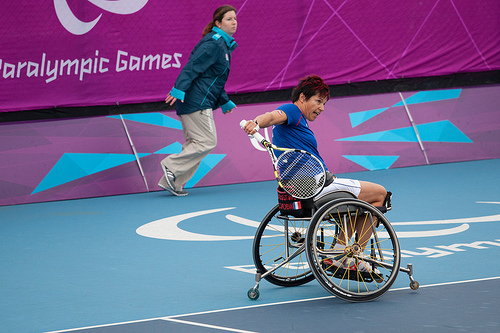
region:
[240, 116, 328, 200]
tennis racket in woman's hand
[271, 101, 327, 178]
blue t-shirt on woman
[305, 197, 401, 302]
wheel on woman's wheelchair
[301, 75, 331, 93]
dark red highlights in woman's hair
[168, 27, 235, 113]
blue jacket on girl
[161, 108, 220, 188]
khaki pants on girl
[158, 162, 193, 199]
beige sneakers on girl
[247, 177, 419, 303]
wheelchair with woman sitting in it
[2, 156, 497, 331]
floor of tennis court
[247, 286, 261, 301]
stabilizing wheel on wheelchair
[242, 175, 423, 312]
part of a wheelchair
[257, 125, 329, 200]
a large tennis racket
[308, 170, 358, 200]
part of a woman's white shorts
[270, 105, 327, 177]
part of a short sleeve blue shirt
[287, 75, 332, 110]
a woman's short cut hair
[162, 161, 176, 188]
part of a woman's tennis shoe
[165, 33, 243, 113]
a large blue jacket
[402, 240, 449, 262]
a white letter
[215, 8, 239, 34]
the head of a woman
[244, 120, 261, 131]
the hand of a woman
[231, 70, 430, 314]
tennis player in a wheelchair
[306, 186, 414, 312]
tire on a wheelchair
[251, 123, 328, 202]
tennis racket in man's hand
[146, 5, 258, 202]
woman in back of a court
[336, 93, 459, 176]
blue design on a banner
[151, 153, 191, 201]
sneakers of a woman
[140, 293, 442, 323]
blue ground of a tennis court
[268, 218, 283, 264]
spokes of a wheel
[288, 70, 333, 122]
face of a tennis player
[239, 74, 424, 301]
Woman in wheelchair with tennis racket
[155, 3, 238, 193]
Woman wearing dark teal and light teal coat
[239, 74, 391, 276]
Woman with red streaks in hair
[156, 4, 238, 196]
Woman with brown hair worn in ponytail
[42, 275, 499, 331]
Tennis court painted dark teal with white lines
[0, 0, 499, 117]
Magenta, white and pink colored banner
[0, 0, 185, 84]
Paralympic Games logo in white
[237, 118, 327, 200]
White and black colored tennis racket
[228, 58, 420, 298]
This is a female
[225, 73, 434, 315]
The woman is playing tennis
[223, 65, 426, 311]
She is playing tennis in a wheelchair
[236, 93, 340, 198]
She is holding a tennis racket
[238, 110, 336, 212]
The tennis racket is in her right hand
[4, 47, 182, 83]
This is the Paralympic Games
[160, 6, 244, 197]
Woman behind the tennis player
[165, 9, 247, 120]
Woman is wearing a jacket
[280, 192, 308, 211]
A flag on her wheelchair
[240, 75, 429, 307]
Woman is turned sideways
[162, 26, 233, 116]
dark blue jacket with turquoise cuffs and collar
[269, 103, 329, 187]
dark blue tee shirt with red stripe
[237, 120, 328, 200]
black and white racket with white handle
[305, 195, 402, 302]
large wheel with metal spokes and silver trim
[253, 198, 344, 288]
large wheel with metal spokes and silver trim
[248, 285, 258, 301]
small wheel with brown tire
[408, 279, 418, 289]
small wheel with brown tire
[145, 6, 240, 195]
woman running along the blue sidelines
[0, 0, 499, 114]
white letters on a pink background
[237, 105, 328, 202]
The racket in the lady hand.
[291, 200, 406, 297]
The wheel on the chair.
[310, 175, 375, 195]
The shorts are white.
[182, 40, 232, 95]
The jacket is blue.